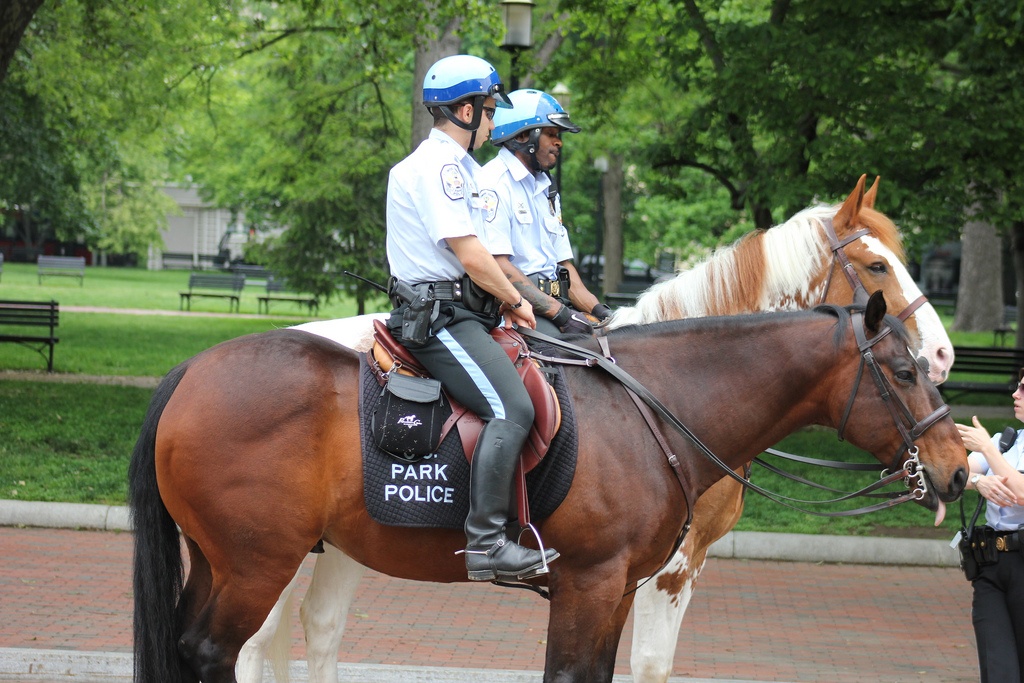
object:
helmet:
[421, 54, 512, 109]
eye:
[863, 261, 888, 273]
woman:
[952, 375, 1024, 682]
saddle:
[358, 319, 579, 529]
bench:
[0, 296, 61, 370]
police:
[384, 54, 616, 581]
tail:
[128, 355, 186, 683]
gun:
[391, 281, 437, 347]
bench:
[176, 275, 245, 314]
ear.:
[832, 173, 867, 230]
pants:
[959, 530, 1020, 683]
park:
[0, 0, 1024, 532]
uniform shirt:
[384, 127, 501, 287]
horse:
[128, 285, 972, 681]